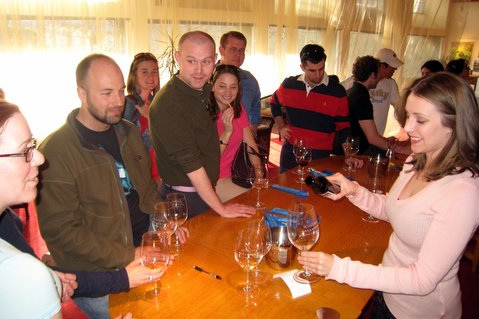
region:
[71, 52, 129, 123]
a balding man's head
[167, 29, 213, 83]
a balding man's head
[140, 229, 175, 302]
a large partially full wine glass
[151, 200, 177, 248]
a large partially full wine glass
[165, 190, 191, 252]
a large partially full wine glass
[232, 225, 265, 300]
a large partially full wine glass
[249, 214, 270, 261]
a large partially full wine glass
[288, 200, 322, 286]
a large partially full wine glass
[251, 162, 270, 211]
a large partially full wine glass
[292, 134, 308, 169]
a large partially full wine glass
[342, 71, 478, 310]
this is a lady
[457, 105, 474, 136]
part of the hair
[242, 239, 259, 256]
part of the glass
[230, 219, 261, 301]
the glass is empty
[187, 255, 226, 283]
this is a pen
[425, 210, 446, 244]
part of the blouse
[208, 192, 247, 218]
hand is in front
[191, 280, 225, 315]
table is wooden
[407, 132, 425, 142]
the mouth is open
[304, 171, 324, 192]
this is a bottle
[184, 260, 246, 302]
the table is shiny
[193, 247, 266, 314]
the table is shiny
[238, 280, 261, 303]
the table is shiny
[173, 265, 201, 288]
the table is shiny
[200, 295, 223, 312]
the table is shiny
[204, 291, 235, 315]
the table is shiny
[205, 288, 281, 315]
the table is shiny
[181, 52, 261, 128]
the girl is smiling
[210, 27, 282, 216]
the girl is smiling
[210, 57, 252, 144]
the girl is smiling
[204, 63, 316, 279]
the girl is smiling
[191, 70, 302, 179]
the girl is smiling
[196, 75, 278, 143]
the girl is smiling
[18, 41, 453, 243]
people watching a woman pour wine into glasses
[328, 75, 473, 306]
woman in long sleeved pink shirt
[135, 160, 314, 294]
empty wine glasses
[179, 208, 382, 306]
wine glasses on a wooden table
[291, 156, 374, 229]
woman holding wine in right hand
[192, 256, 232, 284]
pen on the table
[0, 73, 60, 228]
woman with glasses on the left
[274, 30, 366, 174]
man in red and black striped shirt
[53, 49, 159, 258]
man in brown jacket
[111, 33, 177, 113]
woman in background with sunglasses on head